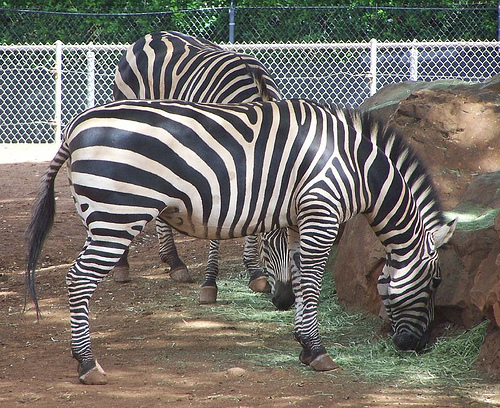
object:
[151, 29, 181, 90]
stripes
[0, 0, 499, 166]
fence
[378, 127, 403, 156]
ground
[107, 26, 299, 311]
zebras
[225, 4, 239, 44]
fencepost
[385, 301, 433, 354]
jackson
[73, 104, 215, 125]
stripe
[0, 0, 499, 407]
toilet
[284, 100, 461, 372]
american flag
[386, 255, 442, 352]
face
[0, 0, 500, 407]
photo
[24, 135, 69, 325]
tail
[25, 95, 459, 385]
zebra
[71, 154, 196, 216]
stripe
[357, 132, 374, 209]
stripe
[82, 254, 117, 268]
stripe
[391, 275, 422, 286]
stripe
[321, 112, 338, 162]
stripe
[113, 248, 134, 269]
leg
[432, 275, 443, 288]
eye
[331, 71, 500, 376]
rock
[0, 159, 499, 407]
ground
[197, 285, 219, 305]
brown hoof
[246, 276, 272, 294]
brown hoof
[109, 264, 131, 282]
brown hoof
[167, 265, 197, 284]
brown hoof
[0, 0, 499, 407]
enclosure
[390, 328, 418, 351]
mouth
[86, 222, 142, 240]
stripe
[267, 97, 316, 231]
stripe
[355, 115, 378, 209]
stripe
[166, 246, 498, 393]
grass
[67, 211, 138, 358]
leg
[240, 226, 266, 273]
leg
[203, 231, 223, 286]
leg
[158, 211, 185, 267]
leg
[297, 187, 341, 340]
leg